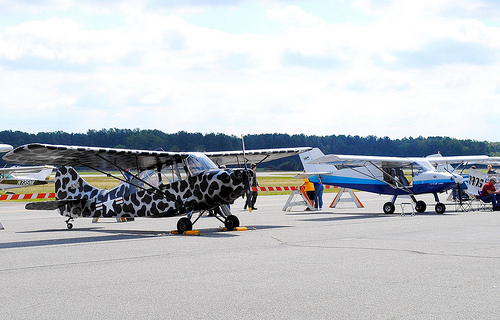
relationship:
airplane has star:
[2, 142, 314, 235] [101, 194, 117, 212]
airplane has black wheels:
[2, 142, 314, 235] [174, 209, 246, 239]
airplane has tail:
[298, 147, 482, 215] [291, 139, 335, 189]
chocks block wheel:
[185, 227, 198, 237] [172, 212, 196, 234]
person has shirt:
[294, 160, 321, 212] [293, 180, 321, 197]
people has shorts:
[314, 183, 324, 211] [305, 187, 316, 204]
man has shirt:
[475, 177, 497, 211] [452, 174, 482, 205]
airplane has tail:
[300, 147, 461, 210] [301, 149, 336, 177]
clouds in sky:
[1, 4, 498, 142] [3, 0, 495, 140]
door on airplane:
[382, 166, 414, 186] [302, 154, 463, 213]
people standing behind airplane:
[314, 183, 324, 211] [288, 143, 485, 217]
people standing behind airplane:
[313, 178, 323, 208] [288, 143, 485, 217]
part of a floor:
[239, 273, 355, 320] [370, 259, 403, 295]